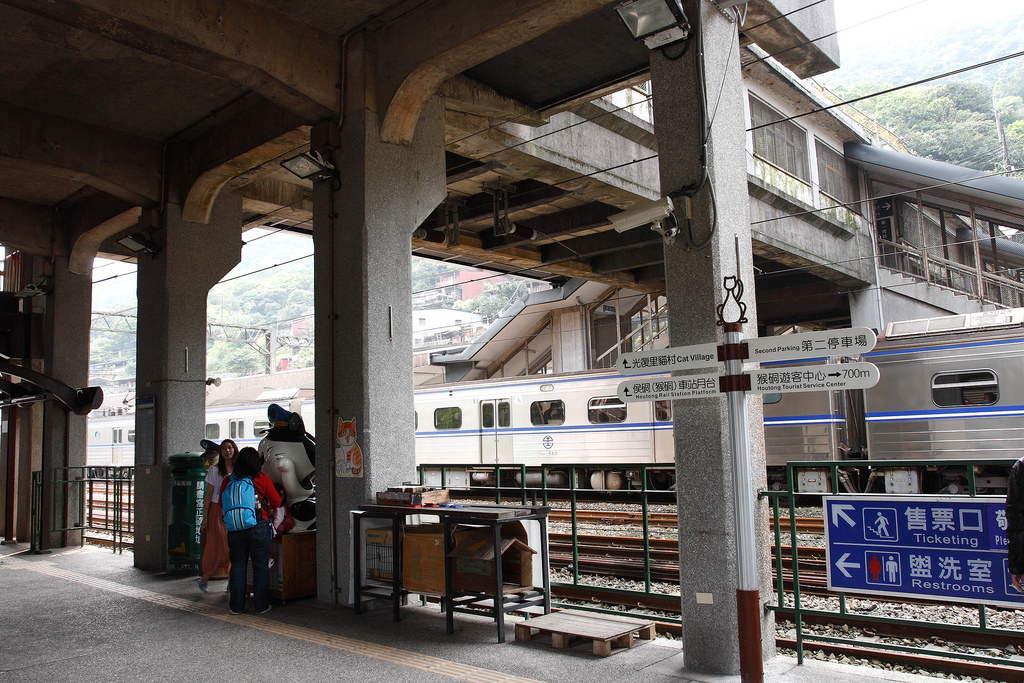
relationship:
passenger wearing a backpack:
[217, 446, 280, 615] [218, 474, 258, 529]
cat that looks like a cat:
[715, 275, 747, 326] [691, 268, 752, 336]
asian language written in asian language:
[616, 326, 881, 402] [609, 335, 886, 390]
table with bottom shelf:
[352, 480, 567, 655] [378, 513, 512, 598]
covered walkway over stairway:
[721, 46, 1005, 295] [853, 134, 1020, 297]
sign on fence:
[825, 497, 1020, 621] [414, 458, 1006, 636]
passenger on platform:
[217, 446, 280, 615] [0, 542, 1024, 683]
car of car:
[397, 340, 719, 515] [87, 307, 1024, 496]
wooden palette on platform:
[514, 588, 646, 669] [8, 541, 927, 663]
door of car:
[481, 391, 529, 474] [87, 307, 1024, 496]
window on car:
[928, 357, 1004, 418] [87, 307, 1024, 496]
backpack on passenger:
[221, 473, 257, 531] [216, 432, 294, 599]